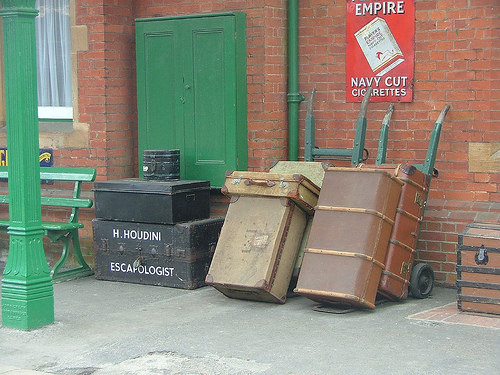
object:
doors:
[142, 18, 229, 189]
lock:
[476, 243, 488, 265]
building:
[0, 0, 495, 287]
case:
[455, 220, 500, 315]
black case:
[87, 218, 223, 290]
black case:
[89, 176, 213, 221]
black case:
[133, 145, 182, 182]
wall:
[0, 0, 497, 286]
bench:
[0, 160, 103, 278]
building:
[87, 1, 499, 183]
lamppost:
[0, 0, 53, 331]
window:
[33, 0, 72, 121]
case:
[90, 179, 210, 225]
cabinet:
[129, 9, 245, 190]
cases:
[292, 162, 422, 310]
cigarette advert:
[346, 0, 414, 103]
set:
[0, 0, 499, 332]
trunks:
[288, 0, 301, 162]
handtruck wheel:
[410, 261, 434, 298]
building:
[0, 0, 499, 331]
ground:
[0, 280, 499, 371]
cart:
[292, 103, 451, 311]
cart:
[204, 87, 373, 305]